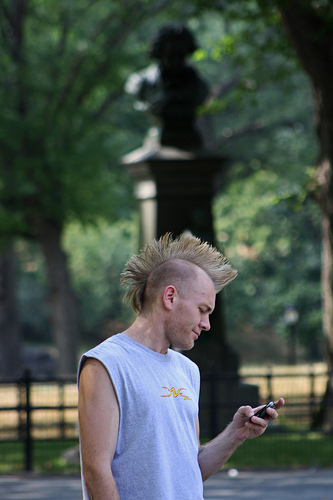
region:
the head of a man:
[120, 237, 252, 340]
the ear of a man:
[152, 278, 187, 312]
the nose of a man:
[193, 316, 220, 331]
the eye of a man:
[196, 296, 207, 319]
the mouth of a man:
[184, 316, 206, 345]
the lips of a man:
[178, 326, 220, 339]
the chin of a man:
[167, 337, 199, 368]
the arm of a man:
[72, 354, 166, 487]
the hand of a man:
[218, 388, 301, 441]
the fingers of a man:
[229, 395, 291, 433]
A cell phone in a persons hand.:
[244, 400, 274, 424]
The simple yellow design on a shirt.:
[161, 384, 191, 403]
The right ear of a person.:
[163, 279, 173, 311]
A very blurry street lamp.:
[284, 308, 296, 363]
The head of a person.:
[117, 231, 238, 348]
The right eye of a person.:
[197, 305, 204, 315]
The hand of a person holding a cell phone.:
[201, 398, 281, 478]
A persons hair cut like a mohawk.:
[120, 233, 238, 309]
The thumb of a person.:
[235, 404, 254, 417]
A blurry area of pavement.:
[1, 470, 330, 499]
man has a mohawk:
[46, 188, 291, 499]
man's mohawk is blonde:
[101, 227, 245, 337]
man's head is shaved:
[133, 251, 212, 319]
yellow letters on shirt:
[144, 378, 205, 416]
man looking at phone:
[53, 227, 288, 496]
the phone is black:
[243, 393, 300, 438]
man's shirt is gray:
[66, 318, 232, 499]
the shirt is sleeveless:
[71, 332, 229, 498]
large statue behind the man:
[117, 25, 263, 426]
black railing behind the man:
[0, 366, 332, 478]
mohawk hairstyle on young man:
[120, 226, 230, 319]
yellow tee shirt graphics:
[156, 384, 194, 402]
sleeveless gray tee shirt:
[76, 331, 205, 498]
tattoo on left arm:
[193, 440, 206, 463]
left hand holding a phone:
[224, 393, 284, 441]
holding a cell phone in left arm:
[195, 391, 286, 481]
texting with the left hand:
[223, 391, 284, 447]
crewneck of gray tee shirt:
[113, 328, 171, 365]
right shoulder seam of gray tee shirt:
[81, 334, 117, 358]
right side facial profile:
[116, 229, 237, 350]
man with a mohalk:
[76, 226, 283, 493]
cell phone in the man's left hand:
[226, 392, 281, 442]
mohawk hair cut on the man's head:
[117, 232, 240, 308]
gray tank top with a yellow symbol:
[66, 338, 208, 497]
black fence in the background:
[0, 371, 327, 469]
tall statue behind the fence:
[119, 18, 259, 439]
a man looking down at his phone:
[79, 225, 284, 495]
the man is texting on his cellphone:
[231, 390, 286, 442]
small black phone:
[226, 394, 285, 435]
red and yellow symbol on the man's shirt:
[153, 381, 198, 403]